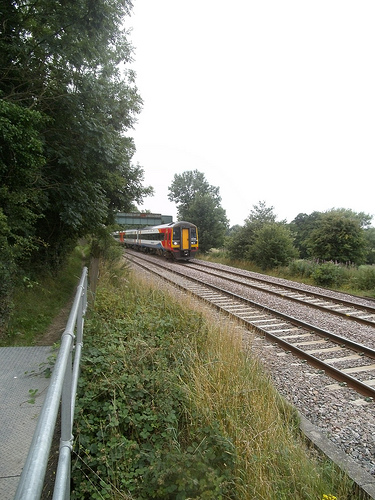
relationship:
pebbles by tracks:
[293, 374, 366, 459] [128, 244, 372, 481]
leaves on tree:
[44, 88, 147, 254] [4, 7, 148, 277]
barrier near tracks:
[304, 424, 369, 486] [192, 298, 354, 415]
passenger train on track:
[111, 220, 199, 261] [144, 255, 374, 384]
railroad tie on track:
[273, 329, 315, 338] [126, 242, 371, 397]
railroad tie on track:
[258, 322, 288, 329] [159, 262, 374, 399]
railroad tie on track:
[326, 353, 364, 367] [175, 277, 290, 365]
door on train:
[181, 228, 188, 249] [106, 220, 199, 262]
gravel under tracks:
[179, 263, 371, 346] [230, 267, 292, 311]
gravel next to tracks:
[179, 263, 371, 346] [230, 267, 292, 311]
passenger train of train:
[111, 220, 199, 261] [99, 188, 222, 286]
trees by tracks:
[238, 200, 369, 277] [126, 228, 354, 358]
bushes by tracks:
[274, 258, 372, 298] [126, 228, 354, 358]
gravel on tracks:
[161, 260, 375, 346] [116, 245, 373, 496]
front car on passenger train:
[130, 223, 202, 261] [111, 213, 210, 268]